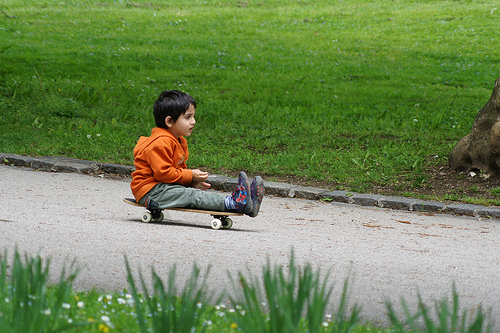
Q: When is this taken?
A: During the daytime.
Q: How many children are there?
A: One.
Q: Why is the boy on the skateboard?
A: To have fun.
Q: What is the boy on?
A: A skateboard.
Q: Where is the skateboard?
A: Underneath the boy.